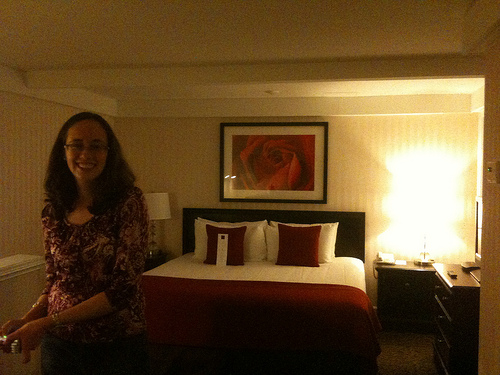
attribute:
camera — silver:
[1, 334, 19, 357]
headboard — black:
[173, 202, 362, 263]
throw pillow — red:
[275, 225, 325, 266]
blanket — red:
[139, 271, 369, 372]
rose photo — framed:
[213, 118, 329, 199]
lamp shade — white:
[146, 187, 175, 216]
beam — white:
[24, 54, 485, 90]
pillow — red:
[268, 222, 328, 272]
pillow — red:
[206, 227, 244, 274]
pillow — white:
[186, 214, 258, 268]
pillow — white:
[262, 218, 347, 274]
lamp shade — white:
[142, 189, 172, 223]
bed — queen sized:
[153, 204, 382, 369]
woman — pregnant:
[12, 124, 153, 373]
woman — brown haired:
[4, 114, 154, 368]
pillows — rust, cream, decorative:
[187, 212, 265, 271]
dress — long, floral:
[35, 185, 153, 363]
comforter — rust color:
[135, 270, 377, 370]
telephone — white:
[371, 248, 402, 267]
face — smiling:
[57, 113, 110, 179]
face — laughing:
[59, 111, 111, 181]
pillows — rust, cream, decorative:
[266, 218, 339, 266]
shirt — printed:
[31, 183, 151, 337]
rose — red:
[239, 135, 305, 186]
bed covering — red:
[135, 273, 380, 371]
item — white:
[2, 334, 22, 354]